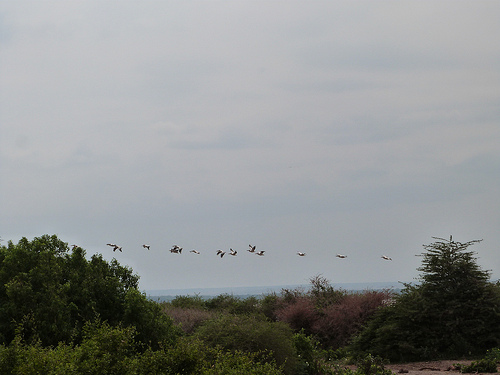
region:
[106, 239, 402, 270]
a flock of flying birds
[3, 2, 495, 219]
a cloudy gray sky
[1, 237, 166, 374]
a green brush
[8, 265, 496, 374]
a cluster of green and red shrubs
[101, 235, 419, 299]
birds flying over a distant sea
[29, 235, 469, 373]
birds flying over shrubs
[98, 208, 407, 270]
birds flying on a cloudy day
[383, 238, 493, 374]
a tall green tree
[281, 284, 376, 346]
a reddish brush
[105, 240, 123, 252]
a flying white bird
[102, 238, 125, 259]
bird flying in sky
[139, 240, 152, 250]
bird flying in sky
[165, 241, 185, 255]
bird flying in sky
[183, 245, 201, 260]
bird flying in sky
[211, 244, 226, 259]
bird flying in sky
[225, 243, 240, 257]
bird flying in sky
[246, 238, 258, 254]
bird flying in sky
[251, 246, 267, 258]
bird flying in sky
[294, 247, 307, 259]
bird flying in sky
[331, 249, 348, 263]
bird flying in sky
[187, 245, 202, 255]
bird flying in sky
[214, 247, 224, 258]
bird flying in sky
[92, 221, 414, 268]
skein of geese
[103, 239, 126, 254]
individual goose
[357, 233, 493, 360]
ever green trees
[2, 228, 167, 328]
deciduous green leafed trees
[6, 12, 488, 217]
cloudy to overcast skies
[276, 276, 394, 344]
small red bushes growing in foreground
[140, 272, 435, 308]
plateau on the horizon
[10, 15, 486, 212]
alto stratus clouds in sky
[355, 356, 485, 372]
small amount of dirt in foreground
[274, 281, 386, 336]
dead bushes near the evergreen trees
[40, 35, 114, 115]
white clouds in blue sky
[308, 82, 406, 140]
white clouds in blue sky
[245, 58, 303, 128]
white clouds in blue sky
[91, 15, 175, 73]
white clouds in blue sky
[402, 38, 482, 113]
white clouds in blue sky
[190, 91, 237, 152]
white clouds in blue sky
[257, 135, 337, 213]
white clouds in blue sky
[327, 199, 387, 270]
white clouds in blue sky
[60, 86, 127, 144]
white clouds in blue sky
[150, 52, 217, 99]
white clouds in blue sky